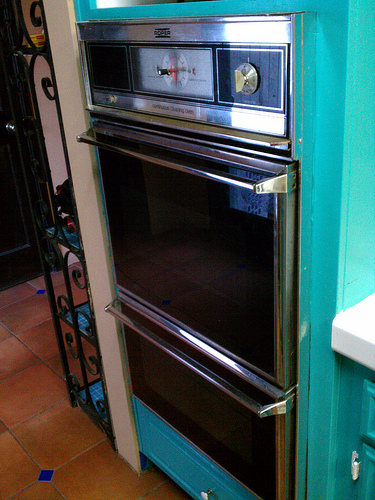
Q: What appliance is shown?
A: Oven.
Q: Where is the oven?
A: In the wall.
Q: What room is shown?
A: Kitchen.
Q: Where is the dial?
A: On the oven.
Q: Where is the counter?
A: Beside the oven.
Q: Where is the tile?
A: On the floor.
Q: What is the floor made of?
A: Tiles.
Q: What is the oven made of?
A: Stainless steel.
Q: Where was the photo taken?
A: Kitchen.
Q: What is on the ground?
A: Brown tile.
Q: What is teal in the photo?
A: Walls.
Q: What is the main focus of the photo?
A: Oven.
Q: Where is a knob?
A: Above stove.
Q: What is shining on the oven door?
A: Light.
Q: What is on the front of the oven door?
A: Glass.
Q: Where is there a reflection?
A: Oven doors.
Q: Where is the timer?
A: On the stove.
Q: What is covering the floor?
A: Brown tiles.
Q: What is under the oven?
A: A drawer.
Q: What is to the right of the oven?
A: Counter.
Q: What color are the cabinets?
A: Turquoise.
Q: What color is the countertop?
A: White.